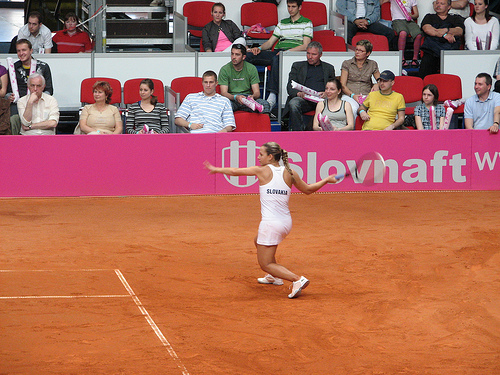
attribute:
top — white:
[253, 161, 293, 215]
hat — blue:
[371, 69, 398, 84]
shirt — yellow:
[356, 89, 409, 134]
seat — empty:
[232, 107, 272, 136]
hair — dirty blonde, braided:
[252, 135, 297, 181]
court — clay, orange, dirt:
[4, 195, 498, 374]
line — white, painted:
[108, 259, 187, 374]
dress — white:
[252, 159, 296, 249]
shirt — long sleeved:
[16, 97, 60, 135]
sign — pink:
[2, 130, 496, 199]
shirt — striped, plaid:
[172, 92, 239, 133]